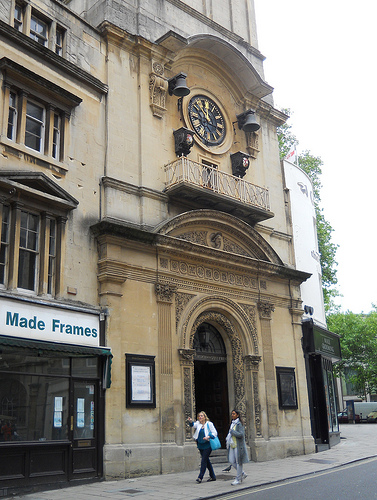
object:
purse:
[207, 421, 222, 450]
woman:
[226, 409, 250, 486]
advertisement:
[0, 296, 100, 347]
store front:
[0, 482, 111, 499]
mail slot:
[78, 440, 91, 447]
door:
[67, 377, 98, 480]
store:
[0, 291, 114, 499]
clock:
[188, 94, 226, 146]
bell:
[236, 108, 261, 132]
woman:
[188, 410, 222, 483]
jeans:
[198, 447, 216, 480]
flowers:
[187, 417, 193, 428]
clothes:
[227, 421, 249, 466]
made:
[6, 311, 45, 330]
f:
[53, 319, 60, 331]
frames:
[52, 319, 97, 337]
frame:
[125, 352, 157, 408]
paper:
[131, 365, 151, 400]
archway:
[178, 294, 260, 355]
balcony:
[162, 155, 275, 222]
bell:
[168, 72, 190, 97]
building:
[62, 0, 343, 482]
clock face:
[182, 85, 235, 154]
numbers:
[192, 100, 221, 141]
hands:
[205, 99, 210, 116]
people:
[187, 409, 249, 486]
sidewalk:
[0, 422, 377, 500]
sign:
[275, 365, 299, 409]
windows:
[0, 170, 79, 297]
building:
[0, 0, 109, 497]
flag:
[286, 141, 298, 166]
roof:
[279, 158, 313, 185]